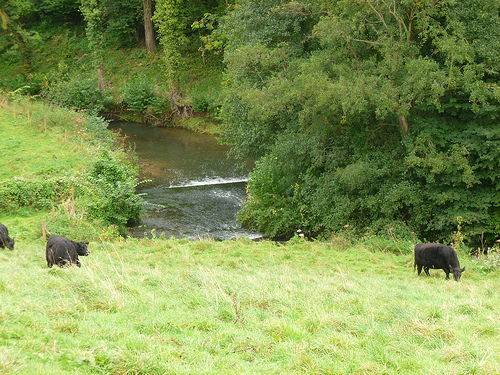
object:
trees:
[75, 1, 110, 94]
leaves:
[336, 153, 387, 197]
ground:
[436, 139, 485, 171]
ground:
[426, 89, 472, 139]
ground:
[404, 132, 455, 162]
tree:
[141, 0, 159, 54]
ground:
[406, 109, 427, 137]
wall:
[246, 86, 263, 126]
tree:
[338, 0, 462, 198]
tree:
[148, 0, 187, 114]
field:
[1, 232, 500, 375]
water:
[105, 119, 267, 243]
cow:
[0, 223, 15, 251]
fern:
[91, 171, 165, 224]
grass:
[0, 88, 500, 375]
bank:
[1, 88, 496, 373]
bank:
[6, 28, 488, 160]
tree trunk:
[140, 0, 157, 55]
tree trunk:
[78, 0, 106, 101]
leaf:
[453, 202, 483, 234]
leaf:
[448, 152, 483, 194]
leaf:
[321, 197, 346, 228]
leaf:
[341, 92, 373, 131]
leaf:
[463, 87, 497, 121]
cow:
[46, 235, 81, 268]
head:
[449, 265, 466, 282]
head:
[77, 240, 90, 256]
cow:
[413, 243, 465, 282]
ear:
[461, 266, 466, 272]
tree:
[238, 122, 495, 239]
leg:
[76, 260, 82, 267]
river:
[91, 119, 253, 235]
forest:
[186, 0, 500, 246]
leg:
[416, 263, 423, 276]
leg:
[423, 266, 431, 276]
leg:
[442, 268, 450, 280]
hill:
[0, 0, 278, 140]